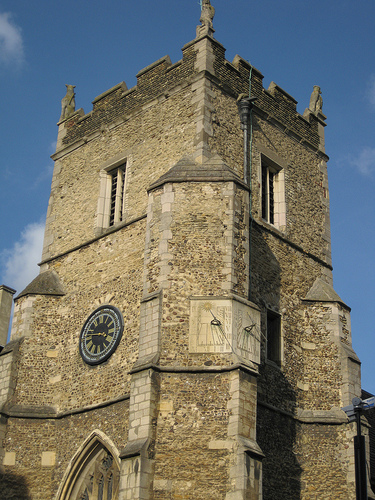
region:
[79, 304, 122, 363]
a clock on the side of a tower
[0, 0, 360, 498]
a brick tower of a castle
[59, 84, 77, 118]
statues are on the top of the tower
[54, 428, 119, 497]
an archway on the tower wall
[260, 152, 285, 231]
a rectangle window on the tower wall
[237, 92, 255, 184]
a metal rain gutter on the side of the tower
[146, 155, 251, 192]
a small roof on the side of the tower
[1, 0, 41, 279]
blue sky's with puffy white clouds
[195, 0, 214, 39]
a statue on the towers roof wall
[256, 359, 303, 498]
a shadow from the sunlight being blocked by a structure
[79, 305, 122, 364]
a black faced clock on the wall of a castle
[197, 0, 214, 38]
a statue on the top of the castle tower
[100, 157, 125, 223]
a rectangle window on the castle tower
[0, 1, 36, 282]
clear blue sky with puffy white clouds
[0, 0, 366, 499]
a castle tower built of bricks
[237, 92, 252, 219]
metal rain gutters on the side of the tower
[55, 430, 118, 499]
an arched window on the side of the tower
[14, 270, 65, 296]
a small roof on the side of the tower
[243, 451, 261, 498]
a painted scene on the wall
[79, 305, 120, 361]
the time displayed on the clock is 3:45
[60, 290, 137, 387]
a clock face on a tower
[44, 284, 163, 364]
the clock has roman numbers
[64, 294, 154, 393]
the numbers are gold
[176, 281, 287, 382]
a sundial on the corner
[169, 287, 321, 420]
this is a decorative sundial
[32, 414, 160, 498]
a stained glass window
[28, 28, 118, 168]
gargoyle on the roof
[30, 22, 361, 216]
the top of a tower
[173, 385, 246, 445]
the bricks are brown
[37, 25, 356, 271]
a castle tower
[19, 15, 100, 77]
The sky is blue.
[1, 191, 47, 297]
The clouds are white.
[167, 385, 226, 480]
The building is made with stone.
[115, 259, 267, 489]
The building is brown.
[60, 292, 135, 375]
The clock is black.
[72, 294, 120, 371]
The clock hands are gold.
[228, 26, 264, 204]
The pipes are silver.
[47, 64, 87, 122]
Gargoyles are on the roof.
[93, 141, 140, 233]
The windows are rectangles.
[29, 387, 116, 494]
The doorway is arched.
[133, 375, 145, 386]
a brick on a building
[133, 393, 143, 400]
a brick on a building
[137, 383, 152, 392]
a brick on a building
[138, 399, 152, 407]
a brick on a building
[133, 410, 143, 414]
a brick on a building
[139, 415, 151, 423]
a brick on a building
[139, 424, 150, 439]
a brick on a building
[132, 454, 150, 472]
a brick on a building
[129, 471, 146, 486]
a brick on a building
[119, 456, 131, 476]
a brick on a building